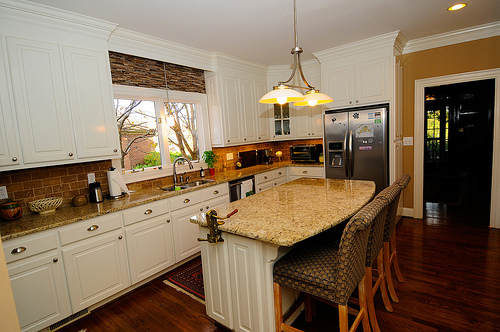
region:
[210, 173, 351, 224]
brown marble counter in kitchen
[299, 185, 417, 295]
brown cushions on chairs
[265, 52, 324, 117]
white lights over counter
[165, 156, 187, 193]
nickel faucet in sink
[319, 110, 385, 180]
steel fridge and freezer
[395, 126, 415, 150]
white light switch on wall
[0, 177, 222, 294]
white drawers under sink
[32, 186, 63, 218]
tan basket on counter near sink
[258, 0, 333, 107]
A light fixture hanging from the ceiling.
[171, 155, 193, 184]
The curved faucet of a sink.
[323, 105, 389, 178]
A brushed steel refrigerator.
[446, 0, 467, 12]
Light fixture in the ceiling.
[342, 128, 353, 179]
Brushed steel handles of a refrigerator.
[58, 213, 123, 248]
Silver handle of a counter's drawer.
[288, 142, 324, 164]
A black toaster over.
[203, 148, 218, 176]
A bright, green plant in a small, red pot.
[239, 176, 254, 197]
A white towel hanging from the dishwasher handle.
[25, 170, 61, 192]
A wall of red bricks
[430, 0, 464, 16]
light fixture on ceiling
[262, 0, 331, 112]
lamp hanging from ceiling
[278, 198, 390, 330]
chair at the counter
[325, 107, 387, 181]
silver refridgerator in kitchen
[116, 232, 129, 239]
knob on the cabinet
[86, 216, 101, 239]
handle on the drawer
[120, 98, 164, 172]
window to the kitchen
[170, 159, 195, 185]
faucet on the sink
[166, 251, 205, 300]
rug on the floor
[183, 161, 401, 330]
island in the middle of the kitchen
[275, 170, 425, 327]
row of three chairs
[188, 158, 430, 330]
chairs pushed in to the island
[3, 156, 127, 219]
wall is made of brick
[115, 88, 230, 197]
windows above the sink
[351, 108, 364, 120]
magnet on the fridge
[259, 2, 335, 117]
light fixture hanging down from the ceiling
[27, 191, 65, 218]
basket on the counter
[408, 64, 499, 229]
door frame is white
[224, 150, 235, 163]
outlet on the wall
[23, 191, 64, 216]
light brown basket on counter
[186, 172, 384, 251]
yellow and white table in middle of kitchen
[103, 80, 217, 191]
two square glass windows with white wooden frame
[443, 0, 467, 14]
circular yellow light in ceiling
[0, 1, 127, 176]
white wooden cabinets above counter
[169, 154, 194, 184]
silver metal sink faucet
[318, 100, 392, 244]
silver metal refrigerator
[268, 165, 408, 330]
chairs with wooden frames and legs next to table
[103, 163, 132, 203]
white paper towel roll on counter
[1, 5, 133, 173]
The upper cabinets to the left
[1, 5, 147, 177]
A set of upper cabinets to the left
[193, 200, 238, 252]
Vice grip on the counter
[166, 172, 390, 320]
Island in the kitchen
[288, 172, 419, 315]
Chairs by the island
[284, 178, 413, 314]
Three chairs by the island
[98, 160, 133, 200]
Paper towels on the counter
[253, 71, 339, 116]
Lights hanging above island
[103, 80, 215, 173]
Window behind the sink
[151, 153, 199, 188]
Silver faucet in the sink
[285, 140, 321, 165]
Toaster oven near the refrigerator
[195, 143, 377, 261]
tan marble counter top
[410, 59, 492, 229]
open door way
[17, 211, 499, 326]
dark brown hardwood floor